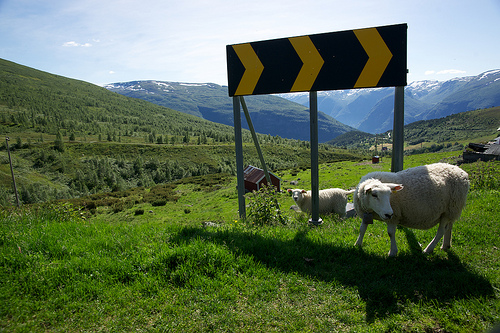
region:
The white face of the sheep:
[356, 172, 404, 220]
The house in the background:
[239, 153, 274, 185]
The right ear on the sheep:
[390, 183, 405, 192]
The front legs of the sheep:
[346, 219, 403, 265]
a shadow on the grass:
[277, 235, 318, 264]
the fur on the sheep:
[408, 175, 452, 214]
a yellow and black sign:
[225, 39, 399, 84]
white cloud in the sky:
[431, 65, 461, 77]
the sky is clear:
[431, 19, 466, 61]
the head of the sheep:
[368, 181, 400, 218]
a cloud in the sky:
[61, 38, 98, 55]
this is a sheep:
[309, 145, 489, 277]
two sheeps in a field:
[258, 133, 492, 277]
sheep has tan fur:
[339, 126, 484, 266]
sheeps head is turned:
[333, 171, 413, 226]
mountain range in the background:
[10, 13, 498, 214]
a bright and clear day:
[10, 5, 490, 330]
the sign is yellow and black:
[211, 22, 436, 118]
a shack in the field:
[220, 135, 290, 230]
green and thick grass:
[76, 228, 180, 285]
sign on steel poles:
[234, 95, 406, 175]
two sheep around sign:
[279, 168, 447, 265]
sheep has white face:
[351, 188, 442, 236]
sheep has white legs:
[378, 225, 450, 260]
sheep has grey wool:
[379, 181, 459, 221]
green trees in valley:
[19, 127, 190, 202]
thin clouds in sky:
[41, 13, 214, 84]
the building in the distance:
[241, 163, 274, 196]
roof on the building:
[241, 164, 274, 184]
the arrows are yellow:
[233, 44, 267, 100]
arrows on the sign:
[225, 31, 419, 89]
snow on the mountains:
[107, 80, 197, 91]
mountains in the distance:
[131, 77, 476, 127]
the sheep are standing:
[293, 172, 473, 255]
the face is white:
[365, 180, 395, 225]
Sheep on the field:
[289, 165, 474, 264]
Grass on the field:
[96, 223, 203, 301]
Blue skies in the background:
[125, 13, 200, 60]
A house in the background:
[227, 144, 281, 202]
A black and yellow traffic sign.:
[218, 16, 413, 236]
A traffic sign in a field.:
[208, 15, 432, 257]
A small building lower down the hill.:
[236, 163, 281, 200]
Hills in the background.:
[133, 67, 498, 138]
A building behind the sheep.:
[458, 125, 499, 162]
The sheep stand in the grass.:
[281, 162, 480, 290]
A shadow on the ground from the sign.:
[201, 225, 493, 317]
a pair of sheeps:
[274, 146, 476, 270]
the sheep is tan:
[340, 150, 486, 270]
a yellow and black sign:
[205, 18, 412, 98]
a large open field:
[17, 57, 476, 331]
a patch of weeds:
[71, 177, 226, 221]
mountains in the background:
[119, 62, 494, 143]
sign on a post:
[199, 25, 431, 227]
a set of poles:
[210, 82, 412, 237]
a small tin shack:
[230, 155, 291, 210]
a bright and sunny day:
[19, 13, 489, 329]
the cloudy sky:
[0, 1, 495, 116]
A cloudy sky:
[1, 1, 498, 108]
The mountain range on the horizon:
[130, 52, 498, 127]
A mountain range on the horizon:
[112, 61, 496, 127]